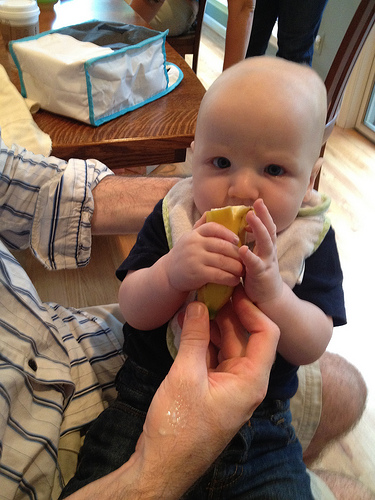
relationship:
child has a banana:
[72, 42, 351, 500] [190, 201, 259, 302]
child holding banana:
[72, 42, 351, 500] [190, 201, 259, 302]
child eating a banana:
[72, 42, 351, 500] [190, 201, 259, 302]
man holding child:
[3, 143, 363, 500] [72, 42, 351, 500]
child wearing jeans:
[72, 42, 351, 500] [75, 365, 314, 499]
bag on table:
[4, 13, 188, 123] [4, 1, 221, 176]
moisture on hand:
[150, 400, 188, 440] [127, 305, 282, 485]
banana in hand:
[190, 201, 259, 302] [166, 219, 240, 292]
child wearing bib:
[72, 42, 351, 500] [158, 184, 330, 310]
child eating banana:
[72, 42, 351, 500] [190, 201, 259, 302]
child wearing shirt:
[72, 42, 351, 500] [104, 196, 346, 395]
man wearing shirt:
[3, 143, 363, 500] [2, 132, 140, 490]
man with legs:
[3, 143, 363, 500] [306, 353, 370, 499]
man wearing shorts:
[3, 143, 363, 500] [288, 351, 330, 499]